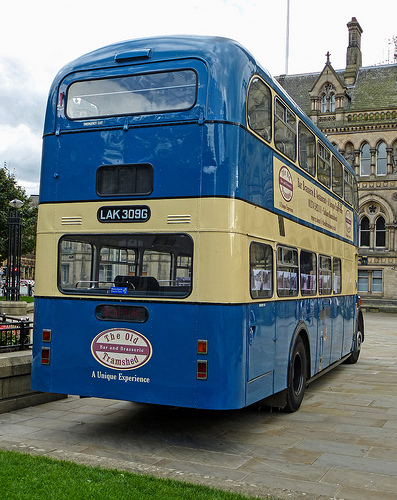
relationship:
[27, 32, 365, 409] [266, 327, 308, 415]
bus has tire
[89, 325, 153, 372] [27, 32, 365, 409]
logo on bus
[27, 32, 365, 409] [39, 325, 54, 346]
bus has light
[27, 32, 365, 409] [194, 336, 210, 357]
bus has light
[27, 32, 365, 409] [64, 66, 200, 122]
bus has window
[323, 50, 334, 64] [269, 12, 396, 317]
cross on building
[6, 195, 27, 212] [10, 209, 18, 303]
light on pole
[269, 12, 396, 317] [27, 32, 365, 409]
church behind bus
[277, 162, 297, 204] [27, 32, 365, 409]
logo on bus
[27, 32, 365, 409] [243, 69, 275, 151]
bus has window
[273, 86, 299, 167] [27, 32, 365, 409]
window on bus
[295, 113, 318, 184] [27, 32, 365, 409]
window on bus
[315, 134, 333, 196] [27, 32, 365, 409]
window on bus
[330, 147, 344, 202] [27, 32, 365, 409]
window on bus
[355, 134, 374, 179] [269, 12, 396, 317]
window on building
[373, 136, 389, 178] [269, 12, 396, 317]
window on building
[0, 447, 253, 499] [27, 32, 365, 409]
grass behind bus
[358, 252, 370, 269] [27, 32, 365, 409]
mirror on bus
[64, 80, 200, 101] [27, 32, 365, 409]
handrail inside bus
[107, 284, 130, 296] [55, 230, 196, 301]
sticker on window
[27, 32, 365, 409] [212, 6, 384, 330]
bus outside of a building